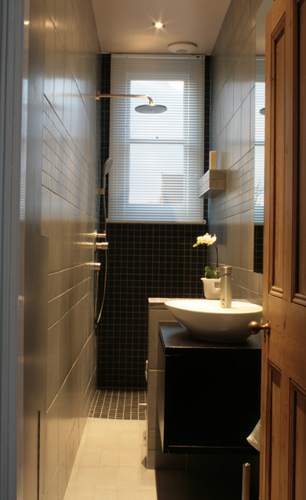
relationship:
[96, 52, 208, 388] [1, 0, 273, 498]
tile on wall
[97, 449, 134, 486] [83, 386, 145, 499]
tile on floor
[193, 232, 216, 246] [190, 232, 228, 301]
bloom on plant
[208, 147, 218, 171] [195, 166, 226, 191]
candle on shelf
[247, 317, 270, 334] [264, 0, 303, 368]
brass knob on door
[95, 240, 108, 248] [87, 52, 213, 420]
knob for shower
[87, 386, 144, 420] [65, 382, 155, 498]
part of floor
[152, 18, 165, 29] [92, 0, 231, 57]
light on ceiling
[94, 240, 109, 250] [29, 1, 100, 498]
knob on wall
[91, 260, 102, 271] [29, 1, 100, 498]
knob on wall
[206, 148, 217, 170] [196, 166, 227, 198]
candle on a shelf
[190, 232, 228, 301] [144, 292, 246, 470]
plant on a table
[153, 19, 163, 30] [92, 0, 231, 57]
light on ceiling